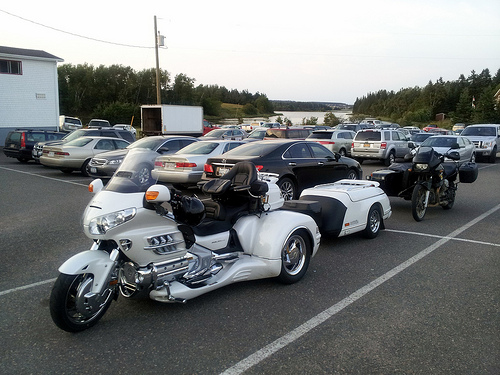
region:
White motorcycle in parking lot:
[42, 175, 322, 338]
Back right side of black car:
[217, 135, 363, 195]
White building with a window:
[0, 42, 60, 127]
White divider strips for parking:
[210, 177, 495, 367]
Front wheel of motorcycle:
[45, 256, 125, 339]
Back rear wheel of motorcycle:
[271, 213, 321, 280]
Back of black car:
[200, 150, 260, 196]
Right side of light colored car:
[61, 133, 136, 168]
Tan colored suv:
[348, 126, 411, 161]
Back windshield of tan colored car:
[355, 125, 382, 146]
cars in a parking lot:
[10, 90, 495, 242]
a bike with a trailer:
[40, 142, 405, 340]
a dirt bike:
[379, 131, 482, 248]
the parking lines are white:
[186, 193, 495, 367]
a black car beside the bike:
[196, 127, 476, 235]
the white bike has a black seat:
[44, 145, 329, 336]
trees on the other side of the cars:
[348, 65, 497, 169]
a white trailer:
[131, 95, 218, 149]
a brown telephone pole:
[141, 14, 178, 120]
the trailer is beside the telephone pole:
[108, 10, 213, 155]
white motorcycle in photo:
[71, 167, 318, 298]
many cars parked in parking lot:
[48, 85, 498, 262]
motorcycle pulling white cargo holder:
[272, 174, 410, 242]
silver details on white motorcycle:
[91, 234, 255, 301]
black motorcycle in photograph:
[385, 142, 475, 214]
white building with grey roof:
[1, 37, 86, 165]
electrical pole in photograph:
[114, 0, 182, 107]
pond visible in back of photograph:
[224, 72, 366, 146]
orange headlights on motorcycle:
[91, 154, 176, 219]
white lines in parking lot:
[8, 145, 363, 373]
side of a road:
[412, 244, 429, 289]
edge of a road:
[386, 266, 427, 314]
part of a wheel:
[53, 256, 69, 294]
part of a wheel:
[288, 174, 302, 195]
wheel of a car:
[352, 166, 353, 173]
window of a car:
[257, 142, 274, 147]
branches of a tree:
[429, 75, 440, 110]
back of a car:
[363, 137, 380, 147]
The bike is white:
[92, 173, 322, 286]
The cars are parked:
[60, 98, 390, 247]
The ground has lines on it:
[371, 247, 451, 367]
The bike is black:
[408, 138, 498, 288]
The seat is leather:
[188, 142, 280, 234]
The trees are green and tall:
[328, 65, 493, 224]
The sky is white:
[245, 19, 357, 119]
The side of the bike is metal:
[136, 235, 271, 316]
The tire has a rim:
[268, 226, 325, 300]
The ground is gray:
[316, 285, 423, 365]